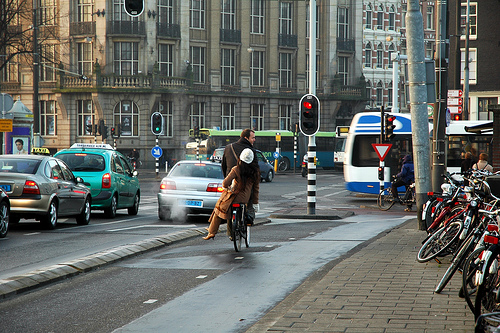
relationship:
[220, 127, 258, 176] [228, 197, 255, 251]
man on a bike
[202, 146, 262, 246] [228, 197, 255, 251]
woman on a bike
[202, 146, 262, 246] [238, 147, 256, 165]
woman wearing a hat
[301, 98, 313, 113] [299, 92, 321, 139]
light part of stoplight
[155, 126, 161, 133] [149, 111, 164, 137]
light part of stoplight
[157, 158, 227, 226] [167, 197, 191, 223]
car blowing smoke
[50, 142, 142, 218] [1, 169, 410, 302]
taxi in street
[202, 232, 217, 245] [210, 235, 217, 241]
shoe has a heel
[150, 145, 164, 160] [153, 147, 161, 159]
sign has an arrow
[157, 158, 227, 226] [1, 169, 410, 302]
car driving down street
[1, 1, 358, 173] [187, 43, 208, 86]
building has window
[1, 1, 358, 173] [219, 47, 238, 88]
building has window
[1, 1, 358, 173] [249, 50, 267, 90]
building has window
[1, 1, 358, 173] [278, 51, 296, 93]
building has window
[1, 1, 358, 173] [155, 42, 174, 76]
building has window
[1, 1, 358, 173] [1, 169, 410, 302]
building off street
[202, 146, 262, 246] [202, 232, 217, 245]
woman wearing shoe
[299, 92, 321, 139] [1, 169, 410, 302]
stoplight in middle of street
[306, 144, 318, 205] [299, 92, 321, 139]
pole has stoplight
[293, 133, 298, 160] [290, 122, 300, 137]
pole has stoplight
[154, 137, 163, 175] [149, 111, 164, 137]
pole has stoplight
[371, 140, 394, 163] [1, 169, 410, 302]
sign on side of street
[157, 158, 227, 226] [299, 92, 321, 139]
car stopped at stoplight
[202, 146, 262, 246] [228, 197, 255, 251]
woman on bike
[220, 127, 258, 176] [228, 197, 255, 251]
man on bike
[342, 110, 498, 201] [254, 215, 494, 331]
bus parked next to sidewalk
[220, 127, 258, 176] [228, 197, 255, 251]
man riding a bike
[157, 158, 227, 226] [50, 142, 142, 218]
car next to taxi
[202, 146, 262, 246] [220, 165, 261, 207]
woman wearing a coat